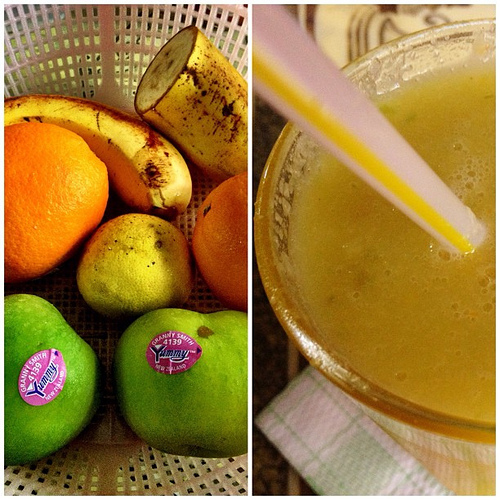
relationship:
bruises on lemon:
[101, 237, 137, 252] [74, 212, 193, 318]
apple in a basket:
[117, 303, 246, 459] [6, 6, 246, 496]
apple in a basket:
[3, 293, 103, 471] [6, 6, 246, 496]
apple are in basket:
[117, 303, 246, 459] [6, 6, 246, 496]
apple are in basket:
[3, 293, 103, 471] [6, 6, 246, 496]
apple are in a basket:
[3, 293, 103, 471] [6, 6, 246, 496]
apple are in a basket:
[117, 303, 246, 455] [6, 6, 246, 496]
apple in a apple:
[3, 293, 103, 471] [117, 303, 246, 459]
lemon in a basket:
[74, 212, 193, 318] [6, 6, 246, 496]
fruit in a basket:
[17, 80, 235, 410] [16, 12, 264, 494]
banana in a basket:
[123, 22, 253, 182] [6, 6, 246, 496]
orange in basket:
[6, 116, 103, 294] [102, 453, 162, 491]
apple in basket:
[117, 303, 246, 459] [97, 453, 183, 491]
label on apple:
[146, 330, 201, 372] [117, 303, 246, 455]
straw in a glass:
[256, 7, 489, 259] [301, 334, 355, 373]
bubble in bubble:
[287, 47, 499, 423] [287, 47, 499, 423]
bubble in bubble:
[475, 274, 490, 289] [287, 47, 499, 423]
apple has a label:
[117, 303, 246, 459] [17, 347, 68, 407]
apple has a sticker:
[117, 303, 246, 459] [145, 334, 205, 374]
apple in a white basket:
[117, 303, 246, 455] [4, 449, 246, 499]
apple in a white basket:
[3, 293, 103, 471] [4, 449, 246, 499]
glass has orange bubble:
[279, 302, 318, 353] [287, 47, 499, 423]